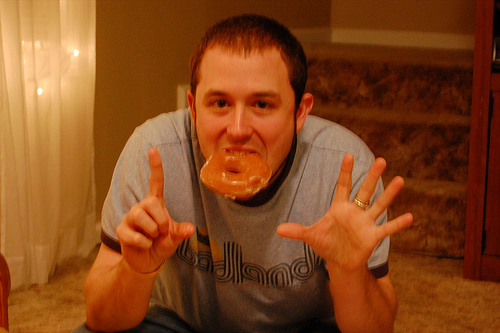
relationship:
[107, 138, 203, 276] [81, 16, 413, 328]
hand of man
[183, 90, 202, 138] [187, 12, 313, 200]
ear of man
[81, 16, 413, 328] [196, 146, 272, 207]
man with doughnut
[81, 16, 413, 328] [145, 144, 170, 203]
man holding finger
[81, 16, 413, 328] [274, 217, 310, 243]
man holding finger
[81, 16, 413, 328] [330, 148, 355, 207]
man holding finger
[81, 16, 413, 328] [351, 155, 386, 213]
man holding finger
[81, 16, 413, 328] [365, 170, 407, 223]
man holding finger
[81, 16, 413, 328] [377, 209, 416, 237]
man holding finger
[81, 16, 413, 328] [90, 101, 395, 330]
man with shirt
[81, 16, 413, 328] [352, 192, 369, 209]
man wearing ring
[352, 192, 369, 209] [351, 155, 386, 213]
ring on finger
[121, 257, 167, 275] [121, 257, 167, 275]
band on band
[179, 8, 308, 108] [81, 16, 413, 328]
hair of man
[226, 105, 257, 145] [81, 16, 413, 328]
nose of man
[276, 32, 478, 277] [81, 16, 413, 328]
steps behind man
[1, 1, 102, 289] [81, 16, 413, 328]
curtains behind man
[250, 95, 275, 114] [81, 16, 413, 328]
eyes of man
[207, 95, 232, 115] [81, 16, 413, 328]
eyes of man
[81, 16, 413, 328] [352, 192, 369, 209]
man has ring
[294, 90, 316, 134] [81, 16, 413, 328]
ear of man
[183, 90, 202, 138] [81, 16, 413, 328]
ear of man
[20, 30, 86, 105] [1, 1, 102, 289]
lamp behind curtains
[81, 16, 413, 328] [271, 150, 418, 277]
man holding 5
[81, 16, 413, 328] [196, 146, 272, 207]
man biting doughnut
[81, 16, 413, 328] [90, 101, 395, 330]
man wearing shirt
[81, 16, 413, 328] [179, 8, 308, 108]
man with hair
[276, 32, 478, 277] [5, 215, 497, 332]
steps with carpet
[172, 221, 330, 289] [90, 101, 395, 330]
logo on shirt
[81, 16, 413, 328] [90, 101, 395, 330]
man in shirt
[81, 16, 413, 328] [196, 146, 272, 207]
man eating doughnut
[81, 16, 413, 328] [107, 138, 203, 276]
man holding hand